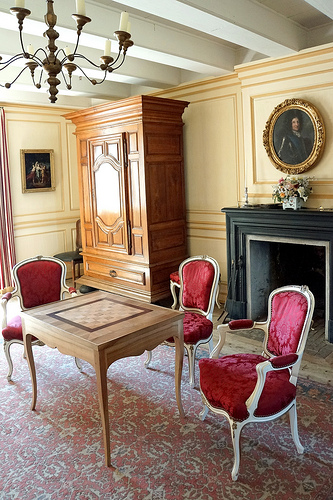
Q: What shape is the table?
A: Square.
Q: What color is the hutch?
A: Brown.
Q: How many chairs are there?
A: 3.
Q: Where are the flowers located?
A: On top of the fire place.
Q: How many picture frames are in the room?
A: 2.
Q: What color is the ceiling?
A: White.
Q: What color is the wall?
A: Bash.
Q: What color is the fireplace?
A: Black.